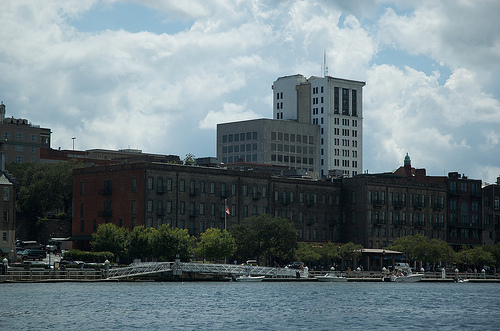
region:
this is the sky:
[398, 21, 491, 141]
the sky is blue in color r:
[106, 10, 159, 30]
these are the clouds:
[111, 38, 200, 103]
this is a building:
[250, 63, 355, 164]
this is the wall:
[280, 83, 305, 119]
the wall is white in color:
[281, 78, 298, 99]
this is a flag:
[223, 188, 238, 226]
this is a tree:
[197, 221, 232, 258]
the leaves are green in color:
[263, 216, 277, 242]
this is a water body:
[236, 273, 316, 329]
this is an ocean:
[0, 272, 496, 327]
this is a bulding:
[75, 157, 345, 239]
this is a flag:
[221, 192, 231, 213]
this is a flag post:
[220, 190, 225, 247]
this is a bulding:
[215, 112, 317, 172]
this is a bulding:
[270, 55, 360, 175]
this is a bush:
[88, 220, 128, 257]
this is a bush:
[134, 223, 192, 258]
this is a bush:
[201, 219, 235, 261]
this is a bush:
[239, 216, 296, 268]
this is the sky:
[95, 12, 161, 28]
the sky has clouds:
[104, 38, 201, 128]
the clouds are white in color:
[82, 50, 214, 129]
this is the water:
[191, 279, 263, 328]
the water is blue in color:
[209, 282, 276, 329]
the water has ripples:
[202, 287, 287, 323]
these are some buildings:
[76, 57, 481, 231]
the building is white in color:
[322, 126, 333, 163]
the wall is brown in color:
[85, 194, 95, 210]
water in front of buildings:
[11, 283, 474, 330]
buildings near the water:
[70, 154, 493, 249]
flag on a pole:
[214, 198, 240, 238]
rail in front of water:
[13, 265, 112, 279]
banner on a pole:
[221, 194, 236, 217]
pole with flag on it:
[221, 205, 231, 231]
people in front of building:
[311, 258, 458, 276]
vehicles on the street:
[21, 226, 64, 261]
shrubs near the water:
[50, 240, 117, 262]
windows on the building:
[223, 130, 261, 159]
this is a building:
[242, 71, 364, 210]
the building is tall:
[243, 69, 367, 166]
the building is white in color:
[237, 79, 361, 171]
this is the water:
[298, 281, 368, 327]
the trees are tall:
[242, 212, 293, 252]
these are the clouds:
[109, 32, 225, 128]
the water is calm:
[318, 281, 358, 316]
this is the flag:
[221, 196, 231, 220]